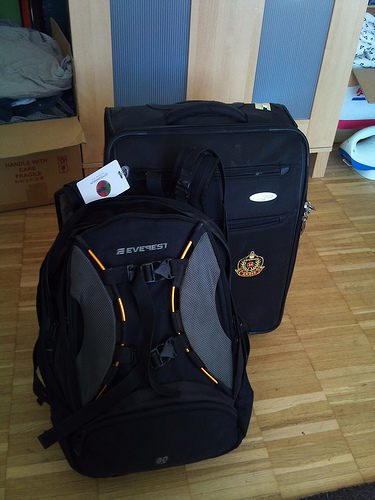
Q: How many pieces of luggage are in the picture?
A: 2.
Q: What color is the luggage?
A: Black.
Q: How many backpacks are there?
A: 1.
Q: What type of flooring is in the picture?
A: Wood.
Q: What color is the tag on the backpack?
A: White.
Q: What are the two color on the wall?
A: Blue and white.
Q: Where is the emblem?
A: On luggage.